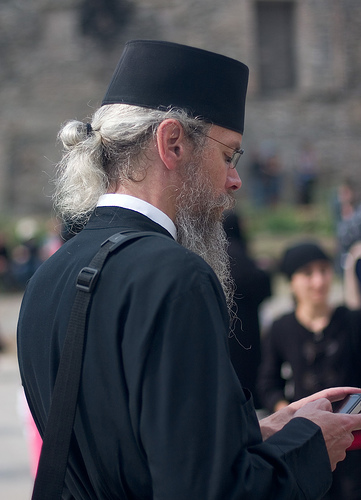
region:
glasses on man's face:
[188, 127, 243, 173]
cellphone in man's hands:
[304, 384, 359, 468]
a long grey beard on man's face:
[178, 180, 252, 351]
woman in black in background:
[253, 243, 359, 412]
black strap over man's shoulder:
[27, 229, 161, 499]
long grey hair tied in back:
[49, 102, 156, 228]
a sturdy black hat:
[102, 37, 250, 137]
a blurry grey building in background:
[0, 0, 359, 215]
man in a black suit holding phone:
[13, 37, 360, 498]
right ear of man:
[156, 118, 184, 173]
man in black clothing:
[17, 38, 271, 499]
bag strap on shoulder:
[26, 226, 206, 498]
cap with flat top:
[104, 38, 249, 134]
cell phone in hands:
[258, 383, 358, 496]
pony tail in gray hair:
[58, 103, 157, 213]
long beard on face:
[174, 126, 244, 322]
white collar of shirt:
[92, 193, 177, 244]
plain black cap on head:
[101, 37, 249, 132]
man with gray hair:
[56, 104, 243, 241]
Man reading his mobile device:
[17, 37, 360, 499]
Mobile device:
[336, 390, 359, 415]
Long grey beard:
[176, 158, 251, 353]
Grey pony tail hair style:
[45, 101, 146, 227]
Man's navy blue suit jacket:
[14, 192, 333, 496]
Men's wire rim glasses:
[179, 120, 241, 169]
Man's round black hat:
[94, 35, 247, 134]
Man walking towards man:
[253, 239, 357, 411]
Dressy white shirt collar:
[91, 190, 182, 240]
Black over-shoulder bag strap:
[30, 227, 176, 498]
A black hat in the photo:
[106, 46, 261, 114]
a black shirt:
[80, 285, 233, 463]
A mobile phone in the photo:
[333, 382, 356, 423]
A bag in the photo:
[62, 269, 93, 420]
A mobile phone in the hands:
[273, 361, 359, 442]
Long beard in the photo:
[178, 169, 248, 315]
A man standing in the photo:
[14, 42, 356, 497]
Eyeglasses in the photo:
[201, 127, 252, 166]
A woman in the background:
[243, 230, 359, 391]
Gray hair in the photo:
[60, 102, 146, 214]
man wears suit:
[15, 38, 359, 499]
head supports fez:
[45, 32, 259, 263]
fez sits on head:
[51, 34, 255, 242]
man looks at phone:
[16, 32, 359, 492]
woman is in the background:
[255, 238, 357, 417]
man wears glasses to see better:
[50, 33, 249, 253]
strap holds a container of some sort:
[26, 228, 185, 499]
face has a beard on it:
[53, 34, 250, 343]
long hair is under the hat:
[54, 30, 243, 240]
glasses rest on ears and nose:
[152, 118, 254, 195]